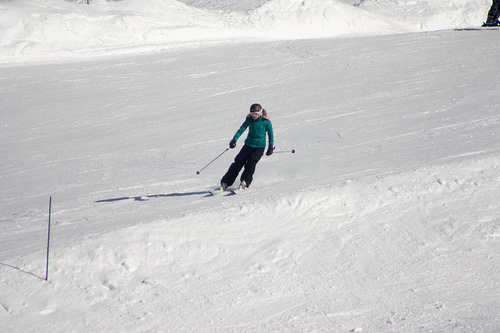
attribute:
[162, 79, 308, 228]
woman — skiing, shadow, turning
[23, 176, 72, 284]
stick — purple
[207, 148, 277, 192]
pant — black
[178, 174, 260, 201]
ski — white, track, pole, poles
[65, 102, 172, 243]
hill — part, edge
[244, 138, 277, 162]
trouser — part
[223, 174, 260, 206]
board — part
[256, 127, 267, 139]
sweater — part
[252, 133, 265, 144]
jacket — part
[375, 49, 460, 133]
slope — part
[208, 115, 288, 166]
lady — skiing, skier, green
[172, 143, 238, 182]
pole — small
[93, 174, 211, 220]
person — shadow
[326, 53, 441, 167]
snow — smooth, shinny, piles, covered, packed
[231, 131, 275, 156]
top — green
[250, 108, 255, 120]
goggle — white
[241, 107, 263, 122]
helmet — dark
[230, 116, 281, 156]
coat — green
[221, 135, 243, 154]
glove — black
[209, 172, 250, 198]
boot — white